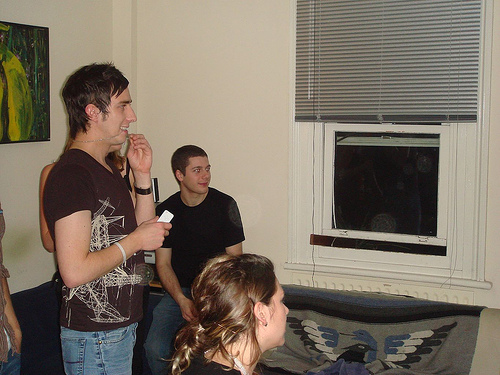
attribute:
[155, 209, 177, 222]
wii controller — white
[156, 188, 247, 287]
shirt — black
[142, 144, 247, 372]
man — playing a game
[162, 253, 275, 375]
hair — blonde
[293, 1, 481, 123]
blinds — white, slatted, gray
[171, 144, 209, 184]
hair — brown, short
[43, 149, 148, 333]
shirt — brown, white, black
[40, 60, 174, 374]
man — playing a game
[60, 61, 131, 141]
hair — dark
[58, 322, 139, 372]
jeans — blue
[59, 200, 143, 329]
designs — white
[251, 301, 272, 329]
ear — pierced